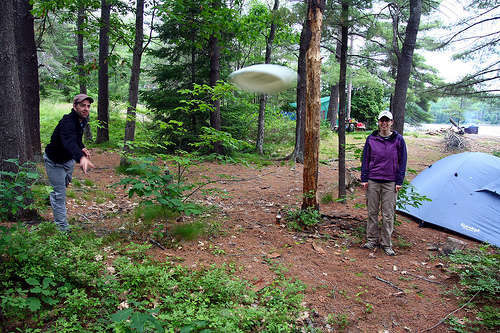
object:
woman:
[358, 108, 409, 257]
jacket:
[357, 128, 409, 187]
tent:
[390, 151, 498, 244]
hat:
[374, 111, 397, 123]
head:
[374, 111, 394, 133]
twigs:
[371, 273, 413, 300]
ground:
[7, 123, 499, 331]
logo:
[457, 222, 483, 235]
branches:
[442, 134, 480, 152]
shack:
[285, 92, 351, 130]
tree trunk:
[1, 0, 45, 226]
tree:
[118, 82, 248, 239]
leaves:
[160, 136, 177, 148]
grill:
[460, 124, 479, 137]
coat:
[43, 110, 89, 166]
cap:
[71, 94, 94, 105]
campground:
[3, 84, 500, 332]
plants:
[0, 220, 110, 300]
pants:
[360, 181, 397, 249]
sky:
[109, 0, 498, 93]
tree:
[94, 1, 110, 145]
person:
[40, 91, 98, 238]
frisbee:
[225, 61, 302, 97]